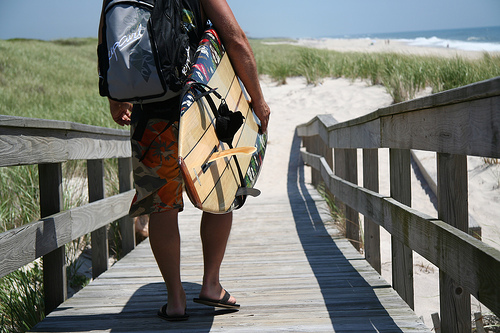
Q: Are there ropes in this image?
A: No, there are no ropes.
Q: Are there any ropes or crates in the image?
A: No, there are no ropes or crates.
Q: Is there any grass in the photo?
A: Yes, there is grass.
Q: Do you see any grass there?
A: Yes, there is grass.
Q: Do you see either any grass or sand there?
A: Yes, there is grass.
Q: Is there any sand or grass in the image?
A: Yes, there is grass.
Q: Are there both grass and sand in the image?
A: Yes, there are both grass and sand.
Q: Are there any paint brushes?
A: No, there are no paint brushes.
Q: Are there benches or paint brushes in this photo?
A: No, there are no paint brushes or benches.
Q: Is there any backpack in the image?
A: Yes, there is a backpack.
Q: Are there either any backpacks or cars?
A: Yes, there is a backpack.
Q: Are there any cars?
A: No, there are no cars.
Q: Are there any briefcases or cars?
A: No, there are no cars or briefcases.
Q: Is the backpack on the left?
A: Yes, the backpack is on the left of the image.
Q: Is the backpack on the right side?
A: No, the backpack is on the left of the image.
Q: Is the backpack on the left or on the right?
A: The backpack is on the left of the image.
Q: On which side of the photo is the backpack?
A: The backpack is on the left of the image.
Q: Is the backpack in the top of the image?
A: Yes, the backpack is in the top of the image.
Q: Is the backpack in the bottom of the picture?
A: No, the backpack is in the top of the image.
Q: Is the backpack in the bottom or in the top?
A: The backpack is in the top of the image.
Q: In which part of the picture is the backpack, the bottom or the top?
A: The backpack is in the top of the image.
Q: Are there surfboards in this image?
A: Yes, there is a surfboard.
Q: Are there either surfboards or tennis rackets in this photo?
A: Yes, there is a surfboard.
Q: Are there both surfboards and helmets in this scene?
A: No, there is a surfboard but no helmets.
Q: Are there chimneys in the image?
A: No, there are no chimneys.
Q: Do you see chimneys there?
A: No, there are no chimneys.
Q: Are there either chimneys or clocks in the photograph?
A: No, there are no chimneys or clocks.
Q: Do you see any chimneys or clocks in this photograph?
A: No, there are no chimneys or clocks.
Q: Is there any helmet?
A: No, there are no helmets.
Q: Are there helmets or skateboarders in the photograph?
A: No, there are no helmets or skateboarders.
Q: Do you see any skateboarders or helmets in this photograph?
A: No, there are no helmets or skateboarders.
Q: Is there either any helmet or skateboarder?
A: No, there are no helmets or skateboarders.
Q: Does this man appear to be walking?
A: Yes, the man is walking.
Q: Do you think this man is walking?
A: Yes, the man is walking.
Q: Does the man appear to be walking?
A: Yes, the man is walking.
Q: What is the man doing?
A: The man is walking.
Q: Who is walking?
A: The man is walking.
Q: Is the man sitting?
A: No, the man is walking.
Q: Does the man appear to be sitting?
A: No, the man is walking.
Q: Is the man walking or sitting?
A: The man is walking.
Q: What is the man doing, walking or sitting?
A: The man is walking.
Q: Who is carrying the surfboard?
A: The man is carrying the surfboard.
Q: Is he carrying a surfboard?
A: Yes, the man is carrying a surfboard.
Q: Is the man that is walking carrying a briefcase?
A: No, the man is carrying a surfboard.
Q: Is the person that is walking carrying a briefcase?
A: No, the man is carrying a surfboard.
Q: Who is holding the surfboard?
A: The man is holding the surfboard.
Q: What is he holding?
A: The man is holding the surfboard.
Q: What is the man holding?
A: The man is holding the surfboard.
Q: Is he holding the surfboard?
A: Yes, the man is holding the surfboard.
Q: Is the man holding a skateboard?
A: No, the man is holding the surfboard.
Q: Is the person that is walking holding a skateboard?
A: No, the man is holding the surfboard.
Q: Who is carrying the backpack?
A: The man is carrying the backpack.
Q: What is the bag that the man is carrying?
A: The bag is a backpack.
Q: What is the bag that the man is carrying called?
A: The bag is a backpack.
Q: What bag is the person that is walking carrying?
A: The man is carrying a backpack.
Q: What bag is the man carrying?
A: The man is carrying a backpack.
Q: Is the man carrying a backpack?
A: Yes, the man is carrying a backpack.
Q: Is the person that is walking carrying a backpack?
A: Yes, the man is carrying a backpack.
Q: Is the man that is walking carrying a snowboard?
A: No, the man is carrying a backpack.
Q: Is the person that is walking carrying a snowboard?
A: No, the man is carrying a backpack.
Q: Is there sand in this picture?
A: Yes, there is sand.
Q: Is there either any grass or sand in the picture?
A: Yes, there is sand.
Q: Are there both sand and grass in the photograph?
A: Yes, there are both sand and grass.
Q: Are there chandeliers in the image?
A: No, there are no chandeliers.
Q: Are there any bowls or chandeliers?
A: No, there are no chandeliers or bowls.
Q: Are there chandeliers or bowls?
A: No, there are no chandeliers or bowls.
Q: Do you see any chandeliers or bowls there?
A: No, there are no chandeliers or bowls.